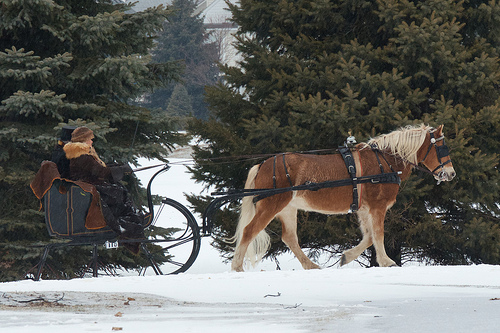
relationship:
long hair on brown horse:
[358, 118, 428, 165] [229, 123, 457, 272]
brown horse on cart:
[229, 123, 457, 272] [22, 135, 207, 277]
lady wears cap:
[62, 127, 132, 228] [69, 123, 93, 140]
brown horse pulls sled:
[229, 123, 457, 272] [23, 177, 205, 266]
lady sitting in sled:
[62, 127, 132, 228] [15, 160, 199, 274]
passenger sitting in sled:
[47, 128, 72, 177] [15, 160, 199, 274]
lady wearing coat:
[62, 127, 132, 228] [53, 140, 133, 213]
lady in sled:
[62, 127, 132, 228] [30, 159, 200, 279]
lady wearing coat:
[62, 125, 144, 233] [62, 140, 125, 186]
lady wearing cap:
[62, 125, 144, 233] [71, 126, 95, 142]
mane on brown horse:
[370, 118, 426, 168] [229, 123, 457, 272]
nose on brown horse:
[440, 162, 465, 184] [229, 123, 457, 272]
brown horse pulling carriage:
[229, 123, 457, 272] [18, 159, 201, 282]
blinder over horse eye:
[435, 139, 450, 164] [433, 140, 451, 160]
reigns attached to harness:
[104, 143, 388, 199] [303, 137, 410, 227]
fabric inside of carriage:
[33, 163, 104, 228] [32, 163, 200, 273]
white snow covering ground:
[17, 246, 474, 331] [2, 130, 498, 331]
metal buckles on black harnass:
[343, 150, 353, 158] [335, 146, 358, 211]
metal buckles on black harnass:
[347, 165, 355, 172] [335, 146, 358, 211]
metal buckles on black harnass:
[349, 182, 358, 191] [335, 146, 358, 211]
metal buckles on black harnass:
[350, 202, 358, 209] [335, 146, 358, 211]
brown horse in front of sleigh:
[229, 123, 457, 272] [28, 145, 203, 278]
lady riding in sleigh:
[62, 127, 132, 228] [36, 159, 198, 279]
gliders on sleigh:
[25, 194, 200, 279] [26, 145, 402, 302]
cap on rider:
[71, 126, 95, 142] [64, 126, 128, 190]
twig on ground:
[4, 274, 89, 317] [2, 130, 498, 331]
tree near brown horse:
[193, 2, 496, 255] [229, 123, 457, 272]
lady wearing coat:
[62, 127, 132, 228] [46, 107, 121, 187]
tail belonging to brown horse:
[222, 165, 270, 270] [229, 123, 457, 272]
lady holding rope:
[62, 127, 132, 228] [97, 160, 170, 241]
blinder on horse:
[432, 139, 452, 159] [220, 123, 471, 220]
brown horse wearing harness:
[229, 123, 457, 272] [234, 141, 403, 214]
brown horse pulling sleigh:
[229, 123, 457, 272] [24, 152, 403, 264]